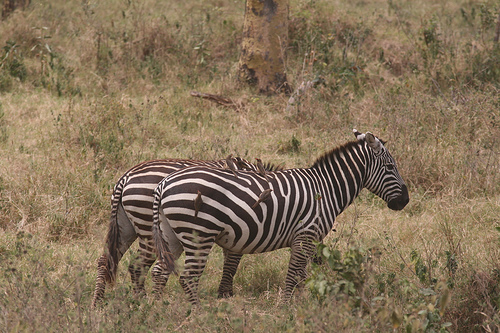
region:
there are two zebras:
[95, 102, 422, 302]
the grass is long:
[45, 51, 160, 132]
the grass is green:
[51, 39, 131, 166]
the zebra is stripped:
[143, 122, 415, 278]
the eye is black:
[381, 158, 401, 180]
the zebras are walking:
[96, 100, 421, 298]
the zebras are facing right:
[76, 90, 422, 299]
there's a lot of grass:
[32, 21, 314, 135]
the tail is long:
[133, 170, 181, 272]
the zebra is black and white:
[140, 123, 430, 290]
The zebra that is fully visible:
[158, 124, 410, 296]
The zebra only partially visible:
[94, 157, 286, 298]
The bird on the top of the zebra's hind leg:
[189, 185, 213, 228]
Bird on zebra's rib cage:
[249, 187, 276, 215]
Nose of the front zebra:
[388, 183, 412, 213]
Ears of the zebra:
[350, 126, 380, 148]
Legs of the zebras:
[88, 227, 319, 301]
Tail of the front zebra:
[149, 185, 178, 277]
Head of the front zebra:
[353, 129, 410, 214]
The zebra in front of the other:
[150, 126, 416, 290]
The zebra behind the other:
[92, 154, 283, 309]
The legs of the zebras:
[98, 217, 327, 308]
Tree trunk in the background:
[235, 0, 298, 91]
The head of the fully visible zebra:
[352, 123, 415, 217]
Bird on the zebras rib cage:
[252, 182, 273, 212]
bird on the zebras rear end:
[184, 184, 206, 224]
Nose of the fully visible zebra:
[389, 187, 412, 215]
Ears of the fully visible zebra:
[353, 129, 378, 152]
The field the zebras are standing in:
[2, 2, 498, 332]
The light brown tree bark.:
[231, 0, 306, 100]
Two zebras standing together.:
[88, 129, 408, 308]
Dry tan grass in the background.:
[0, 115, 80, 330]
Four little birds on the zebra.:
[193, 152, 274, 217]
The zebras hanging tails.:
[109, 178, 169, 273]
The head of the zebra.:
[348, 131, 410, 213]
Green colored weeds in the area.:
[306, 243, 463, 312]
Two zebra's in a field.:
[1, 0, 498, 331]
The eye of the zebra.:
[378, 162, 398, 172]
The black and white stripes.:
[321, 169, 362, 191]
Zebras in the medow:
[83, 119, 416, 321]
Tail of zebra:
[144, 181, 189, 286]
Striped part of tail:
[146, 179, 166, 229]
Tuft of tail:
[146, 226, 181, 278]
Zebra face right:
[148, 119, 428, 316]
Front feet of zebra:
[270, 243, 321, 313]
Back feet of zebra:
[132, 237, 209, 326]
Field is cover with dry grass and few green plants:
[7, 6, 493, 326]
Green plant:
[301, 31, 368, 88]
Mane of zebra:
[302, 134, 362, 166]